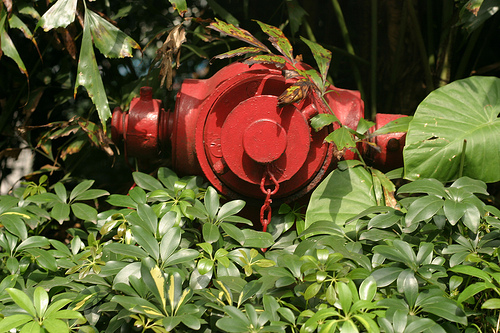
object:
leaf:
[332, 280, 354, 317]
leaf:
[401, 74, 498, 186]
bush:
[0, 183, 499, 332]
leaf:
[398, 177, 453, 197]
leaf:
[443, 197, 467, 224]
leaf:
[448, 177, 488, 192]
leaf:
[416, 242, 432, 259]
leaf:
[365, 210, 402, 227]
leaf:
[394, 179, 451, 201]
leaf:
[366, 236, 416, 271]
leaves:
[32, 177, 106, 227]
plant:
[24, 150, 299, 307]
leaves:
[366, 231, 447, 306]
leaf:
[219, 196, 246, 216]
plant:
[179, 184, 256, 246]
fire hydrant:
[101, 53, 424, 237]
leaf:
[234, 191, 491, 298]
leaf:
[160, 222, 186, 270]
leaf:
[102, 237, 153, 263]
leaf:
[29, 280, 49, 317]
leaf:
[112, 292, 154, 314]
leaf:
[215, 249, 231, 267]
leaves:
[90, 205, 245, 313]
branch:
[206, 14, 368, 169]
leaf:
[371, 267, 400, 286]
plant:
[0, 170, 497, 331]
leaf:
[401, 272, 420, 309]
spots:
[278, 81, 312, 105]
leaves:
[268, 224, 384, 303]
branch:
[457, 139, 469, 178]